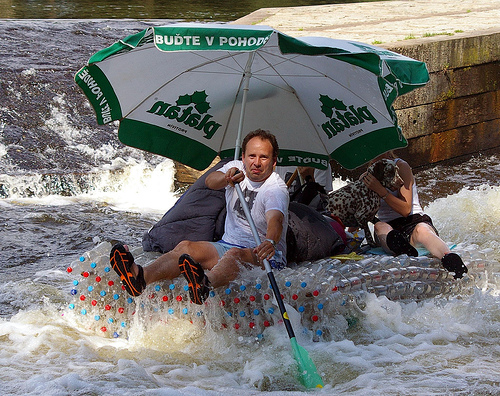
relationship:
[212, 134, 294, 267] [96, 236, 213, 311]
man wearing shoes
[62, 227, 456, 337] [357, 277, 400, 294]
raft of bottles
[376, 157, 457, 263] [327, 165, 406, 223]
woman holding dog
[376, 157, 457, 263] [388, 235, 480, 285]
woman wearing black shoes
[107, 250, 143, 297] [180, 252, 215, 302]
bottom of shoe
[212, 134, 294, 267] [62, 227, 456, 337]
man on raft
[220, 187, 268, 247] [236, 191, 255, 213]
white shirt has graphics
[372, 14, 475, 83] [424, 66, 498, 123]
bricks with moss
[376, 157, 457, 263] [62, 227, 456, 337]
woman on raft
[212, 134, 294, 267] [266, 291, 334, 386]
man using paddle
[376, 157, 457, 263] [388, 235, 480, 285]
woman in black shoes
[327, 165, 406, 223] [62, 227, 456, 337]
dog on raft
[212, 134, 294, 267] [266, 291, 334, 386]
man holding paddle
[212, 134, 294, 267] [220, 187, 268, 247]
man in white shirt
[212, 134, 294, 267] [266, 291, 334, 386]
man with paddle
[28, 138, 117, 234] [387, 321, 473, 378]
water with white caps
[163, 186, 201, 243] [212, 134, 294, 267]
sleeping bag behind man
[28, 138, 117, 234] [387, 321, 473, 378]
water has white caps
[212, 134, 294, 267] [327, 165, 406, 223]
man with dog